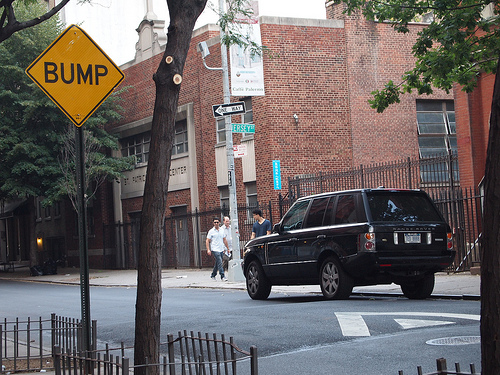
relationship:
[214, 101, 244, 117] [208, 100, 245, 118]
arrow on square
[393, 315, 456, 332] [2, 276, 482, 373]
line on pavement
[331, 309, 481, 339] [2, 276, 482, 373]
line on pavement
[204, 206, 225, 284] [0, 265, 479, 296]
two people walking on sidewalk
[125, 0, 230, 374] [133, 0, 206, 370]
fence around tree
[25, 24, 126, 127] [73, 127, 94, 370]
sign on pole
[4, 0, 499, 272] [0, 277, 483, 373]
brick building across street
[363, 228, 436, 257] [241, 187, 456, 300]
tag on car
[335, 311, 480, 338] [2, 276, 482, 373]
markings on pavement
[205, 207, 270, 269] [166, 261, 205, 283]
people standing on sidewalk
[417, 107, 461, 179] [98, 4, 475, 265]
windows on building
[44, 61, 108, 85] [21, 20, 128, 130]
bump written on sign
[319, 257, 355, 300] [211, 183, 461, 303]
tire on car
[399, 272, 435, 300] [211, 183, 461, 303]
tire on car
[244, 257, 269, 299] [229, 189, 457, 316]
tire on vehicle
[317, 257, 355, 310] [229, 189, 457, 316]
tire on vehicle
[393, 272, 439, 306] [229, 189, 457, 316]
tire on vehicle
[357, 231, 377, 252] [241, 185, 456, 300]
taillight on car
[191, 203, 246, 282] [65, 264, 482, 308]
people walking on sidewalk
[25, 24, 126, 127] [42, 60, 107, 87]
sign reads bump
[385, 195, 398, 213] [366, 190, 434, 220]
sticker on window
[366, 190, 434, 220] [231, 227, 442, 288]
window on suv